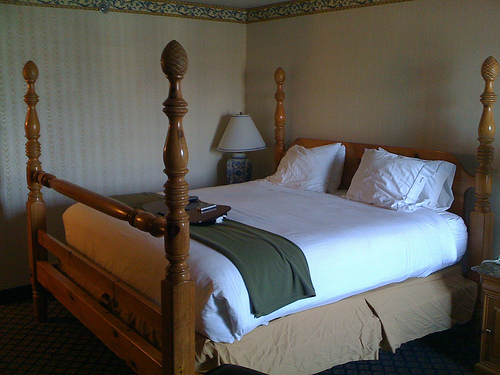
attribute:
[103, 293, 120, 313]
mark — dark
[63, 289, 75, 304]
mark — dark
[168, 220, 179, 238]
mark — dark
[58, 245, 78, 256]
mark — dark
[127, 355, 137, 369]
mark — dark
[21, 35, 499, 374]
bed — tall, holder, made, left side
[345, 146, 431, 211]
pillow — white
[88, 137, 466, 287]
bed — tall, holder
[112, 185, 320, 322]
blanket — green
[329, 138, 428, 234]
pillow — large, white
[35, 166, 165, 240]
pole — long, brown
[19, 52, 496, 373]
bed frame — wood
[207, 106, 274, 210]
holder — tall, bed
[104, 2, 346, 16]
wallpaper — brown, blue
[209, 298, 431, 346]
sheets — tan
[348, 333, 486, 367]
carpet — blue, checkered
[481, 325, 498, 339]
knob — cabinet knob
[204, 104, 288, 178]
lamp — tall, bedside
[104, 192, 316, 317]
cover — green, folded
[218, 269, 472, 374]
skirt — brown, bed skirt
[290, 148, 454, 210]
four pillows — white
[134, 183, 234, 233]
tray — brown, tv tray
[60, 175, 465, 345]
bedsheets — white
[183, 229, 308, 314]
sheet — green, thin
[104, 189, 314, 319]
blanket — long, green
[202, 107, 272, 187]
lamp — white, blue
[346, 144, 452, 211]
pillow — fluffy, white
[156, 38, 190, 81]
post — egg shaped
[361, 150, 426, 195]
pillow — fluffy, inviting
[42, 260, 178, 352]
cabinet — brown, wooden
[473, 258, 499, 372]
table — bedside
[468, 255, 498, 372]
night stand — small